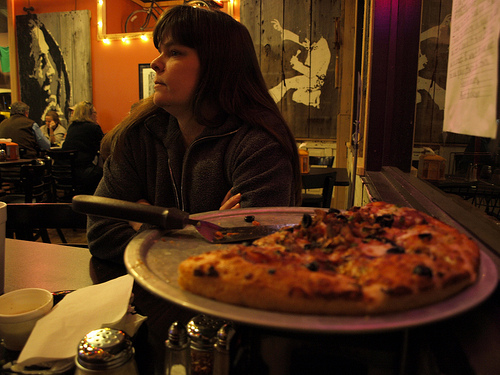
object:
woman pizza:
[87, 0, 500, 336]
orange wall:
[0, 0, 243, 144]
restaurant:
[0, 0, 500, 374]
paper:
[73, 299, 103, 321]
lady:
[88, 4, 302, 374]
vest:
[3, 113, 39, 158]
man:
[0, 102, 52, 160]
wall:
[396, 104, 446, 174]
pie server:
[71, 194, 303, 245]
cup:
[0, 285, 52, 351]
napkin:
[10, 274, 145, 367]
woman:
[65, 99, 107, 195]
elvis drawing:
[267, 17, 332, 110]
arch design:
[175, 201, 482, 316]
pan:
[125, 206, 498, 336]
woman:
[36, 104, 68, 149]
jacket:
[38, 123, 67, 150]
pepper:
[186, 313, 237, 375]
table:
[0, 201, 499, 373]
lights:
[87, 0, 242, 50]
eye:
[167, 48, 184, 58]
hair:
[97, 5, 302, 207]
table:
[299, 167, 352, 207]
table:
[17, 145, 63, 158]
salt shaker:
[73, 326, 140, 374]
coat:
[86, 109, 303, 285]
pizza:
[176, 201, 480, 315]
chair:
[0, 136, 101, 246]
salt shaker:
[164, 320, 187, 374]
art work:
[96, 0, 242, 47]